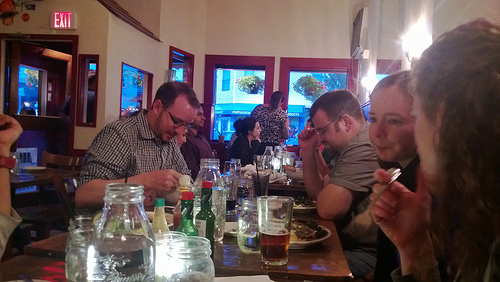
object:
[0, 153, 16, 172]
watch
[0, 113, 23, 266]
arm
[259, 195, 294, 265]
glass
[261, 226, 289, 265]
beer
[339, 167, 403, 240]
fork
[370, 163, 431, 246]
woman's hand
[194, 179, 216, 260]
bottle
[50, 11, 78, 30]
exit sign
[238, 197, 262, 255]
jar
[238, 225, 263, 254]
water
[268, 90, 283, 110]
pony tail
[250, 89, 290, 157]
woman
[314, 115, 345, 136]
glasses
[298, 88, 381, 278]
man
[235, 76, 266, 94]
flowering plants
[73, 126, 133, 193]
shirt sleeves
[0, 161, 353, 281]
table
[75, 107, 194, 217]
shirt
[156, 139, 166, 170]
button down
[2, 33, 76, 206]
door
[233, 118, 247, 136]
pony tails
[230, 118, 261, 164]
women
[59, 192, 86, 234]
straw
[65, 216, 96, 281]
drink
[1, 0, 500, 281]
restaurant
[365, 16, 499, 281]
people eating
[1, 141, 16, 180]
woman's wrist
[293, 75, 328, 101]
red flowers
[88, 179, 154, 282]
bottle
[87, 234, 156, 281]
water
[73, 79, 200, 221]
person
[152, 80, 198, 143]
head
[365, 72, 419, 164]
head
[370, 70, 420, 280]
person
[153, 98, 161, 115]
ear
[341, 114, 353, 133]
ear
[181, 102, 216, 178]
people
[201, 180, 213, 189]
red lid